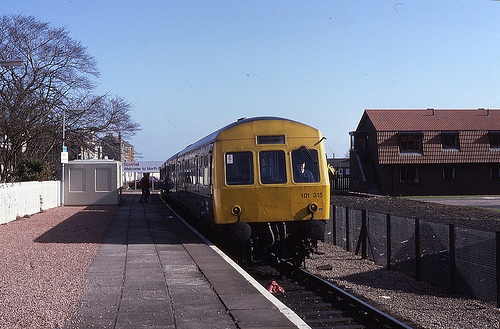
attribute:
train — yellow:
[158, 116, 330, 272]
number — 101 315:
[299, 191, 324, 200]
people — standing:
[140, 170, 153, 202]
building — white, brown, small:
[62, 159, 123, 207]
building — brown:
[348, 109, 499, 197]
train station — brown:
[1, 157, 499, 328]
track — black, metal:
[239, 256, 414, 327]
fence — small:
[324, 202, 500, 306]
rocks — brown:
[1, 205, 117, 328]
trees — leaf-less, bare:
[0, 15, 143, 181]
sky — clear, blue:
[0, 1, 499, 161]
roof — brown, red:
[367, 108, 500, 130]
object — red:
[267, 279, 284, 296]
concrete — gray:
[398, 194, 500, 208]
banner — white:
[121, 160, 162, 173]